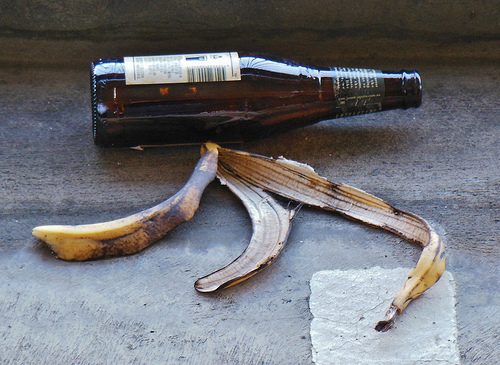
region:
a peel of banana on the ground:
[23, 133, 459, 333]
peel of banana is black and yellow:
[33, 136, 453, 333]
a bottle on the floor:
[79, 45, 439, 150]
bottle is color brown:
[79, 45, 434, 150]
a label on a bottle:
[116, 45, 248, 91]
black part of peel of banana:
[139, 153, 231, 236]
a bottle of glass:
[76, 45, 438, 151]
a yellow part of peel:
[17, 206, 122, 267]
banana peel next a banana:
[29, 43, 465, 333]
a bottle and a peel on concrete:
[1, 15, 495, 360]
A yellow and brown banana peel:
[23, 143, 448, 330]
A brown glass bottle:
[84, 38, 435, 151]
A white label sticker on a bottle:
[119, 52, 251, 90]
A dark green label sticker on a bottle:
[326, 53, 388, 121]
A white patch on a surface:
[304, 265, 461, 364]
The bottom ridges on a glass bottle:
[84, 50, 116, 157]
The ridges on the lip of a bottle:
[394, 65, 424, 115]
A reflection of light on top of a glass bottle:
[91, 55, 421, 84]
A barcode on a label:
[184, 62, 229, 81]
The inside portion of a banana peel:
[191, 146, 429, 306]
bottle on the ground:
[98, 44, 450, 161]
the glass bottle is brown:
[47, 42, 482, 172]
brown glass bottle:
[88, 53, 425, 145]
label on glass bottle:
[121, 51, 241, 81]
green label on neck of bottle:
[332, 65, 385, 115]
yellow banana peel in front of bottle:
[33, 142, 446, 332]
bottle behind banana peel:
[90, 53, 421, 143]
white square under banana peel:
[308, 270, 460, 364]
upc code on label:
[185, 66, 228, 82]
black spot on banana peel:
[326, 178, 345, 192]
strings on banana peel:
[284, 198, 305, 215]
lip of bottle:
[412, 71, 424, 110]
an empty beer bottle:
[90, 51, 422, 151]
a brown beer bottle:
[92, 50, 422, 147]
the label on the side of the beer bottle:
[125, 52, 242, 82]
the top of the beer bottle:
[413, 71, 423, 106]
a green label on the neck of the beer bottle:
[332, 66, 388, 118]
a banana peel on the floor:
[31, 144, 447, 332]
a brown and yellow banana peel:
[31, 143, 446, 333]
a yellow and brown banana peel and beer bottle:
[32, 143, 445, 332]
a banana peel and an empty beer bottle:
[32, 50, 449, 333]